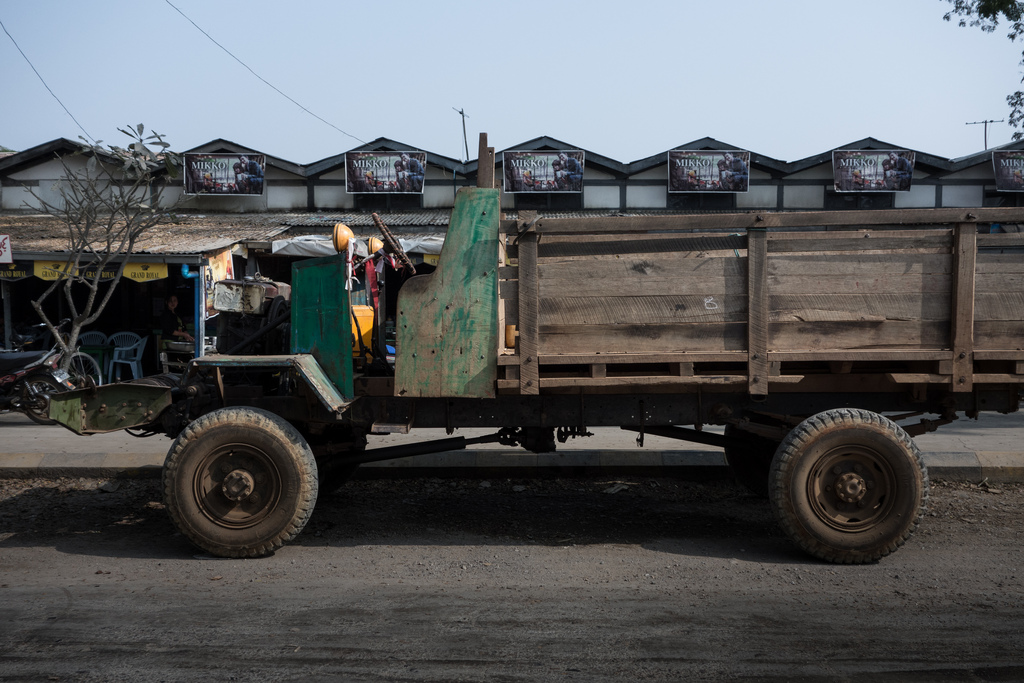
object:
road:
[0, 407, 1024, 683]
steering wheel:
[362, 202, 420, 283]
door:
[354, 213, 529, 403]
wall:
[306, 134, 469, 213]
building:
[306, 128, 475, 219]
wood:
[386, 185, 1023, 406]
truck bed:
[492, 201, 1023, 398]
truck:
[135, 128, 1023, 573]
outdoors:
[0, 0, 1024, 683]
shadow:
[356, 448, 732, 542]